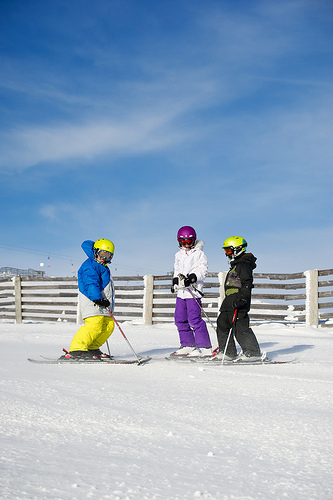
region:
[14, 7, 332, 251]
the sky is blue with white clouds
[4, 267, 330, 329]
a fence is behind the skiers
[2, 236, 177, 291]
a ski lift is in the background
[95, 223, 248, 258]
the skiers have helmets on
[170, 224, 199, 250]
the skier has a purple helmet on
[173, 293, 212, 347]
the skier has purple ski pants on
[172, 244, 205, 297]
the skier has a white down jacket on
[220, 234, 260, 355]
the skier has a black ski outfit on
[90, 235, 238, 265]
all three skiers are wearing snow goggles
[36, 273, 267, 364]
all the skiers have ski poles in their hands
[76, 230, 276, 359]
three skiers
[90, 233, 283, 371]
skiers standing on the snow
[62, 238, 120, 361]
one skier had yellow pants and helmet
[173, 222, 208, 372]
another skier has purple helment and purple pants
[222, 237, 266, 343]
skier wearing yellow helment and black pants.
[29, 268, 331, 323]
fence along the snow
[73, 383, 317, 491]
ground is covered in snow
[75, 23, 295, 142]
the sky is bright blue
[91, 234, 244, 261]
three skiers wearing goggles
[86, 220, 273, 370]
three skiers standing together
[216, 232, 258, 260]
The helmet is green.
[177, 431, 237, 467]
Snow on the ground.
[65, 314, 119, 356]
The pants are yellow.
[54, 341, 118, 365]
The shoes are black.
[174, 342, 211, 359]
The shoes are white.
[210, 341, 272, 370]
The shoes are grey.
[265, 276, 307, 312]
The fence is wooden.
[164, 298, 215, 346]
The pants are purple.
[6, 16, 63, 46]
The sky is blue.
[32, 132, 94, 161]
Cloud in the sky.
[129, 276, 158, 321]
The fence post is white.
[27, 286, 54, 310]
The fence is wooden.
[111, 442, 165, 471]
Snow on the ground.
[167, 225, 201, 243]
The helmet is purple.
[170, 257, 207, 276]
The coat is white.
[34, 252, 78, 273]
Ski lift in the background.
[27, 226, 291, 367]
three people skiing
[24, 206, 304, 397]
three skiers on the slopes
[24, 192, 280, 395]
people taking a break on the slope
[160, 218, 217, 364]
skier in the purple helmet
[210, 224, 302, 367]
the skier in the black snowsuit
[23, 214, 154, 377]
the skier with the blue and grey jacket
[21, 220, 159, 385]
a person wearing yellow ski pants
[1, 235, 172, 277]
the ski lift in the distance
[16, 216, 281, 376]
three young people stopping on the hill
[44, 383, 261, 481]
the white snowy ski slope